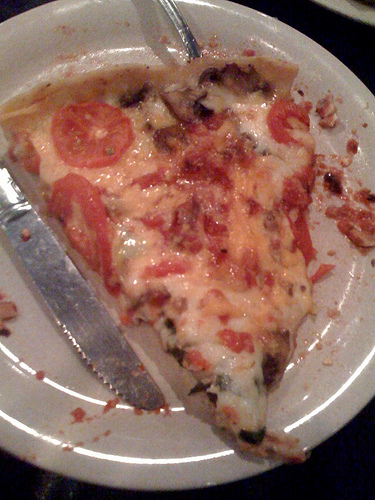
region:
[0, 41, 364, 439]
plate filled with food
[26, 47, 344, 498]
food on top of a white plate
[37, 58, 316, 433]
slice of pizza on a plate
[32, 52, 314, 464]
slice of pizza on a white plate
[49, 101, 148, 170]
slice of tomato on pizza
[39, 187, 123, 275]
slice of tomato on side of pizza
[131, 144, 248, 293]
cheese and sauce on pizza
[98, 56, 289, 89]
crust on edge of pizza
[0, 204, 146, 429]
silver knife on side of plate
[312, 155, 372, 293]
sauce on top of white plate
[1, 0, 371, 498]
THE PLATE IS ROUND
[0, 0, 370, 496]
THE PLATE IS WHITE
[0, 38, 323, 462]
THE PIZZA IS ON THE PLATE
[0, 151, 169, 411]
THE KNIFE IS ON THE PLATE NEXT TO THE PIZZA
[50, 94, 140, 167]
THIS IS A TOMATO ON THE PIZZA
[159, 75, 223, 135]
THIS IS A MUSHROOM ON THE PIZZA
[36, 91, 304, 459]
THIS PIZZA IS VERY CHEESY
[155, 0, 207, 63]
THE FORK IS UNDER THE PIZZA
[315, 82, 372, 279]
THIS PLATE IS VERY MESSY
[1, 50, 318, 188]
THIS IS THIN CRUST PIZZA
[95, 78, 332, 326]
pizza on the plate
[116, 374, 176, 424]
tip of the fork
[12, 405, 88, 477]
rim of the plate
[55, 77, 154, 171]
topping on the pizza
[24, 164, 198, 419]
knife next to the pizza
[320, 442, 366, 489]
table next to plate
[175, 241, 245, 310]
cheese on the pizza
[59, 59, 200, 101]
crust of the pizza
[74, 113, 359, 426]
one piece of pizza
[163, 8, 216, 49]
handle of the pizza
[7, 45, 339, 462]
pizza on a plate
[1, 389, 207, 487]
white plate of a pizza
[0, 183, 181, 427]
knife on a plate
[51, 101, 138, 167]
tomato on a pizza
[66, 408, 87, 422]
sauce dropping on plate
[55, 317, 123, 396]
serrated ridge of a knife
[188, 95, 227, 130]
olive on a pizza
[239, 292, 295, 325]
melted cheese on a pizza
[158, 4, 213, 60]
handle of a fork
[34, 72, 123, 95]
crust of a pizza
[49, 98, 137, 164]
A tomato on pizza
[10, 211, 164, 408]
The end of a butter knife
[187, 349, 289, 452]
The tip of pizza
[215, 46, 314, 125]
The corner of pizza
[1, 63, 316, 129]
The crust of pizza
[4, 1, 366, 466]
A pizza on a plate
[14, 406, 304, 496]
The edge of white plate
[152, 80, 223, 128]
Mushroom on pizza topping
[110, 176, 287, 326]
Pizza cheese and sauce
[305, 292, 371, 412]
Edge of white plate